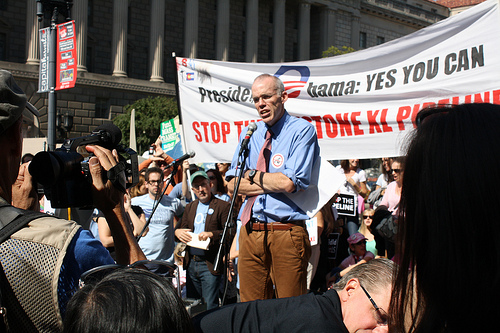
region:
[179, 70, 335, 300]
the man is giving a speech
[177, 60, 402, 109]
the man is campaigning for Obama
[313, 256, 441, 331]
this person is wearing glasses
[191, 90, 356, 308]
the man is wearing a blue shirt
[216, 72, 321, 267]
the man is wearing brown pants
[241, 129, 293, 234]
the man is wearing a reddish/pink tie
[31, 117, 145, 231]
this person has a video cam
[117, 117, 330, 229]
the man is speaking into a microphone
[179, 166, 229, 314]
this man is wearing a green cap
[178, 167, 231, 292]
the man is wearing a brown jacket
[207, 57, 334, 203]
Man has gray hair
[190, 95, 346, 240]
Man is wearing a blue dress shirt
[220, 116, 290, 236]
Man is wearing a tie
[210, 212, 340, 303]
Man is wearing brown pants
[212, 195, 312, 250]
Man is wearing a brown belt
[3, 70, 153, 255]
Person is holding a camera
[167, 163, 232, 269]
Man in the background is wearing a cap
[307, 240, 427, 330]
Person is wearing sunglasses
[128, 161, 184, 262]
Man in the background is wearing eyeglasses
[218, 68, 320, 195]
Man in the foreground is wearing eyeglasses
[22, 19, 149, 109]
the pole has two pennants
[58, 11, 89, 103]
the one pennant is red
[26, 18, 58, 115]
the other pennant is grey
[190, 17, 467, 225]
the campaign sign is white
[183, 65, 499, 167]
the sign also has red letters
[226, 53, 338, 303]
his bodu language says he is closed off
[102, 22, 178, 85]
the building behind him has lots of columns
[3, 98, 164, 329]
this person is video taping the speech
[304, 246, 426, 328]
this person wears glasses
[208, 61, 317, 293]
man making speech to crowd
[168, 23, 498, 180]
political banner behind man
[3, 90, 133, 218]
photographer taking video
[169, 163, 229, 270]
man wearing green cap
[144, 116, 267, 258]
two microphones in front of man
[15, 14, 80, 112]
small banners hanging on pole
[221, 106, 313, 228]
sleeves rolled up on shirt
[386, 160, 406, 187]
woman wearing sunglasses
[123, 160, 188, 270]
man wearing blue shirt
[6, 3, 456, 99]
large building in background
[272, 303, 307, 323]
part of a coat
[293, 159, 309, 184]
part of a blue shirt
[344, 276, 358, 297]
right ear of a man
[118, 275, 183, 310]
hair of a woman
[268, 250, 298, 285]
part of a trouser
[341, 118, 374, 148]
part of a banner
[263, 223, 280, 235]
part of a belt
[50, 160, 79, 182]
part of a camera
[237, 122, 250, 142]
part of a microphone